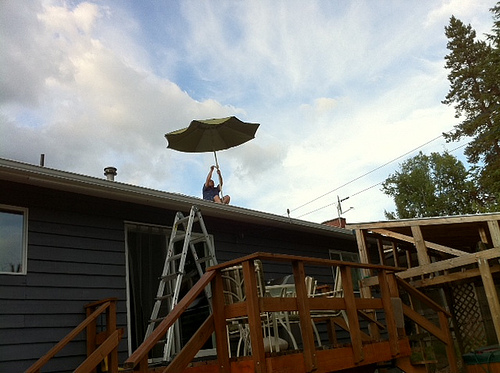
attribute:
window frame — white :
[0, 203, 29, 274]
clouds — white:
[346, 64, 426, 139]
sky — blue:
[143, 22, 274, 134]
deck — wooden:
[22, 250, 460, 372]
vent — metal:
[104, 158, 135, 185]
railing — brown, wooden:
[190, 236, 426, 367]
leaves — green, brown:
[380, 151, 483, 218]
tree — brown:
[438, 14, 498, 204]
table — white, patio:
[254, 285, 288, 355]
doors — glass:
[120, 217, 223, 362]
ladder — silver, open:
[128, 214, 256, 331]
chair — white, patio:
[319, 264, 359, 333]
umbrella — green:
[167, 109, 258, 156]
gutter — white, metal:
[22, 149, 164, 207]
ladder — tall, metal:
[144, 205, 216, 362]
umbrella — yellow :
[162, 114, 260, 151]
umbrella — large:
[153, 112, 268, 150]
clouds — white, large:
[23, 20, 175, 165]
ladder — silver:
[144, 207, 208, 354]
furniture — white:
[216, 259, 299, 353]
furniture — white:
[254, 280, 304, 349]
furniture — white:
[296, 265, 356, 349]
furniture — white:
[263, 270, 324, 350]